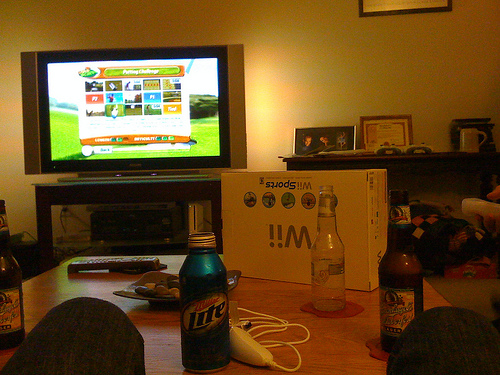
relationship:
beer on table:
[172, 231, 232, 375] [23, 244, 473, 374]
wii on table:
[235, 308, 296, 366] [23, 244, 473, 374]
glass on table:
[307, 180, 351, 315] [23, 244, 473, 374]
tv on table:
[19, 44, 250, 167] [21, 173, 220, 247]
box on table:
[218, 171, 391, 294] [23, 244, 473, 374]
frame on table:
[351, 111, 425, 155] [287, 141, 498, 219]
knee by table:
[21, 286, 145, 375] [23, 244, 473, 374]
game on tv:
[61, 69, 192, 135] [19, 44, 250, 167]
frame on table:
[359, 114, 414, 149] [287, 141, 498, 219]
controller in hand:
[464, 184, 494, 219] [487, 189, 498, 191]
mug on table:
[461, 128, 482, 153] [287, 141, 498, 219]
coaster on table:
[298, 299, 364, 321] [23, 244, 473, 374]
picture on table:
[290, 125, 363, 155] [287, 141, 498, 219]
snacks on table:
[133, 271, 228, 302] [23, 244, 473, 374]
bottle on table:
[372, 187, 421, 344] [23, 244, 473, 374]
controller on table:
[464, 184, 494, 219] [23, 244, 473, 374]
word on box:
[258, 216, 316, 253] [218, 171, 391, 294]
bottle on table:
[307, 180, 351, 315] [23, 244, 473, 374]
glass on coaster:
[307, 180, 351, 315] [298, 299, 364, 321]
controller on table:
[227, 294, 305, 372] [23, 244, 473, 374]